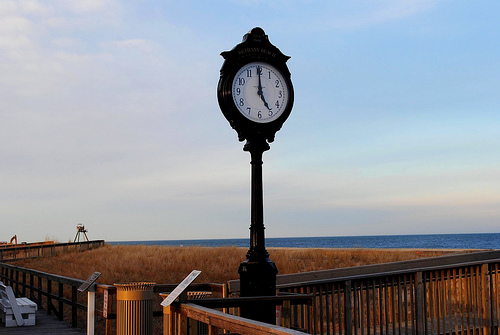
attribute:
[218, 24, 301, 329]
clock — fancy, tall, black, 5 oclock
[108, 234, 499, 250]
water — blue, open, dark blue, smooth, placid, ocean, surface, calm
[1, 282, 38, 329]
chair — wooden, white, folding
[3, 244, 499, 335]
fence — wood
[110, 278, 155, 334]
trash can — metal, beige, brown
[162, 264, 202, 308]
sign — metal, larger, white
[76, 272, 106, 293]
sign — smaller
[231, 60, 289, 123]
face — white, large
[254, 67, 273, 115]
hands — black, metal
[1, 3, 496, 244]
sky — blue, clear, partially cloudy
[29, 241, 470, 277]
grass — dry, brown, sea grass, tall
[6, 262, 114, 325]
guard rail — metal, gray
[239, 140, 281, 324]
pole — metal, black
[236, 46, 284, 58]
writing — white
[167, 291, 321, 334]
railing — wooden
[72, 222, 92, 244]
contraption — tall, yellow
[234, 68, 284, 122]
numbers — black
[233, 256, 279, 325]
stand — black